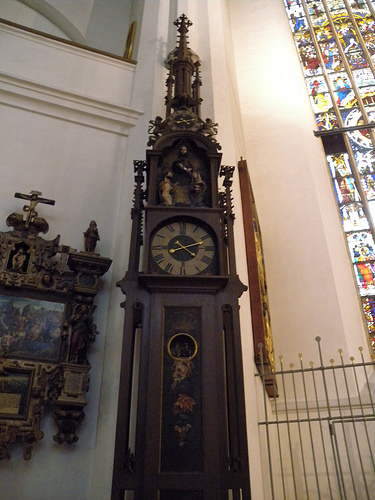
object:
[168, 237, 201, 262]
hand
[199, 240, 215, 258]
mark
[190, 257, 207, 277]
numbers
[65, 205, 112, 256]
statue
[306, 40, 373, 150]
window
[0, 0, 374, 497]
church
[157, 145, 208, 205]
ornament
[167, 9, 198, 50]
cross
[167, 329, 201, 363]
circle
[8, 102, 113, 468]
wall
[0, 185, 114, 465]
frame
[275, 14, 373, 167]
window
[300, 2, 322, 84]
bars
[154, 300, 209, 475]
design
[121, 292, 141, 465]
slot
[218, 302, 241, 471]
slot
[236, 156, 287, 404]
picture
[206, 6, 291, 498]
wall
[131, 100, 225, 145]
images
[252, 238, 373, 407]
stained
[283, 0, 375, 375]
panel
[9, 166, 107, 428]
religious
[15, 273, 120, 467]
wall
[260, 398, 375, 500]
gate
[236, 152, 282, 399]
artwork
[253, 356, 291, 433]
wall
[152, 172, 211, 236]
religious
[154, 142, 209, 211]
religious figurines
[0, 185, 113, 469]
religions painting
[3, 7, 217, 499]
wall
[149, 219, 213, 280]
roman numerals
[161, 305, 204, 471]
religious drawings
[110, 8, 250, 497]
clock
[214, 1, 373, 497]
wall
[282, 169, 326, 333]
decoration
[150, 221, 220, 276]
roman numerals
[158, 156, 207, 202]
statues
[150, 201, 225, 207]
shelf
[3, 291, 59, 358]
portrait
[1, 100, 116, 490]
wall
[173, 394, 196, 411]
leaves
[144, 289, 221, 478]
front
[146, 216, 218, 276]
clock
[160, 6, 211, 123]
steeple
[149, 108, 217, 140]
ornaments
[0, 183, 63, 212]
cross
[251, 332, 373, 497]
bar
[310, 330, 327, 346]
balls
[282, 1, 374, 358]
windows